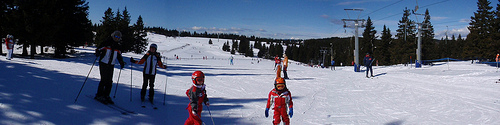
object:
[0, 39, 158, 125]
slope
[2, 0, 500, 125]
resort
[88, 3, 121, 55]
trees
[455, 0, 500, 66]
trees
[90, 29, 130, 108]
adults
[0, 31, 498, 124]
snow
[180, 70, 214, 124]
child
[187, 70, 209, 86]
helmet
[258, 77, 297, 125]
child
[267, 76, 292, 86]
helmet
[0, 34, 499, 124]
ground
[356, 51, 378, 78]
people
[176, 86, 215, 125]
snowsuit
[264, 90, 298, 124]
snowsuit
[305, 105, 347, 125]
tracks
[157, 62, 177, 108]
poles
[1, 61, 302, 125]
shadow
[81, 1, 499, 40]
sky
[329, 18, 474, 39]
clouds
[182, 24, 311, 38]
clouds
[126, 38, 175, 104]
parent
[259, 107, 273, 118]
gloves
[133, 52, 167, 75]
coat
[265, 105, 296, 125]
pants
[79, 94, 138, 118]
skis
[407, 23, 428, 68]
pole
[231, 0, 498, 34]
lift